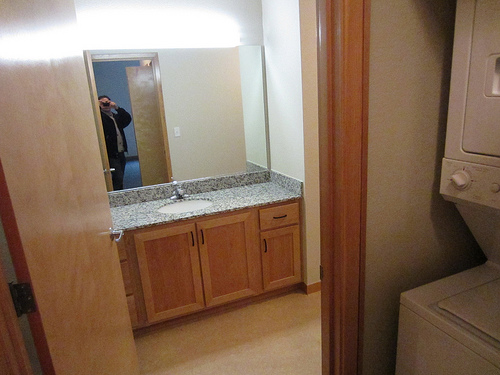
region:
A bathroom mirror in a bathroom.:
[86, 43, 248, 198]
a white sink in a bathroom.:
[156, 194, 217, 219]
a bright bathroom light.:
[67, 0, 257, 47]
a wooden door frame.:
[313, 5, 374, 372]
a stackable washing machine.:
[384, 234, 498, 372]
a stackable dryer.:
[430, 0, 497, 260]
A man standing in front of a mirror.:
[95, 87, 140, 190]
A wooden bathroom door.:
[3, 0, 145, 361]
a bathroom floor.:
[136, 282, 321, 372]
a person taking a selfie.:
[95, 89, 140, 197]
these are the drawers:
[195, 216, 288, 303]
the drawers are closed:
[195, 225, 258, 287]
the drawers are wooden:
[154, 223, 251, 285]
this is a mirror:
[123, 70, 234, 152]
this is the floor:
[240, 305, 302, 372]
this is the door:
[21, 121, 98, 230]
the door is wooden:
[13, 121, 85, 230]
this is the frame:
[320, 70, 367, 114]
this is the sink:
[166, 192, 205, 214]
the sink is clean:
[155, 191, 213, 214]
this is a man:
[98, 88, 140, 153]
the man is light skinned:
[101, 100, 115, 108]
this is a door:
[25, 157, 83, 270]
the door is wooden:
[24, 77, 64, 162]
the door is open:
[31, 92, 63, 136]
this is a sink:
[166, 197, 205, 214]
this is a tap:
[168, 178, 192, 201]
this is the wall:
[216, 26, 300, 98]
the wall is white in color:
[271, 9, 300, 56]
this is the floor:
[231, 319, 272, 366]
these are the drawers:
[148, 230, 270, 312]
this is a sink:
[159, 179, 202, 214]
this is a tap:
[167, 179, 185, 196]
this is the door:
[94, 56, 349, 303]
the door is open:
[102, 110, 373, 313]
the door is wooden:
[7, 139, 104, 264]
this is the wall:
[380, 73, 437, 155]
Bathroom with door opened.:
[2, 0, 495, 370]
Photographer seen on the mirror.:
[96, 90, 136, 192]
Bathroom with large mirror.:
[82, 35, 268, 190]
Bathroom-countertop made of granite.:
[105, 170, 305, 225]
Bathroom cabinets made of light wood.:
[105, 200, 310, 330]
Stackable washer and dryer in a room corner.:
[385, 5, 495, 370]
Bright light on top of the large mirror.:
[80, 5, 245, 50]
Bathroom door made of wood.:
[0, 51, 140, 366]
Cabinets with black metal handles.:
[186, 225, 211, 250]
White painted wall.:
[271, 1, 318, 171]